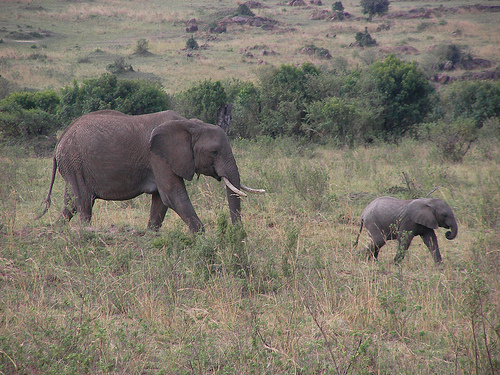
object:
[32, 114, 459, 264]
animals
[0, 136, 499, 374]
field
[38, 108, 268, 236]
elephant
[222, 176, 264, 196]
tusks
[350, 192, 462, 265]
elephant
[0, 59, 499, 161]
trees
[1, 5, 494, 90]
field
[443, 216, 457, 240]
trunk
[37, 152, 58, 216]
tail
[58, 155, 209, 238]
legs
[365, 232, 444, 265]
legs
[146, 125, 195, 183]
ear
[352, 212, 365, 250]
tail